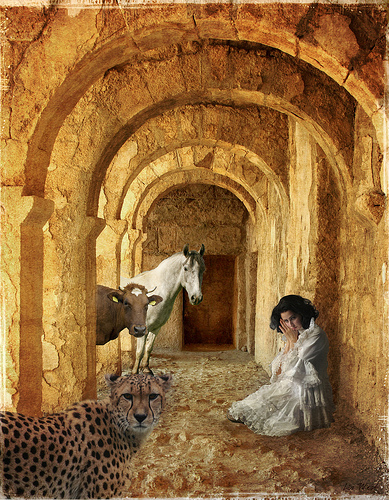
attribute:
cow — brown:
[93, 282, 162, 348]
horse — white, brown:
[132, 242, 206, 374]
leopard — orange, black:
[6, 369, 169, 500]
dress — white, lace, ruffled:
[230, 323, 335, 439]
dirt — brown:
[102, 339, 375, 493]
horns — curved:
[117, 281, 157, 295]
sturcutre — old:
[1, 1, 386, 469]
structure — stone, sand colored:
[1, 2, 385, 469]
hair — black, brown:
[270, 294, 320, 333]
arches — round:
[4, 5, 382, 450]